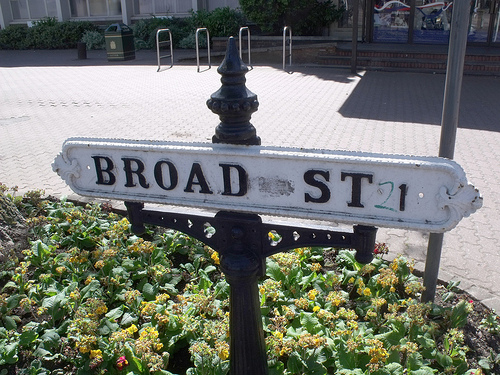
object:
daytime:
[1, 1, 494, 368]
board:
[48, 136, 486, 234]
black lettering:
[90, 154, 247, 197]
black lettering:
[302, 169, 407, 211]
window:
[413, 0, 452, 44]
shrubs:
[135, 35, 151, 48]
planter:
[1, 39, 331, 60]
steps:
[315, 54, 499, 77]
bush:
[27, 16, 99, 50]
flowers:
[101, 315, 178, 369]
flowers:
[288, 260, 473, 374]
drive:
[0, 52, 500, 307]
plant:
[0, 26, 30, 49]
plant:
[238, 0, 351, 36]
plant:
[203, 8, 233, 36]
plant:
[186, 7, 206, 33]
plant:
[78, 32, 107, 49]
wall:
[1, 2, 249, 24]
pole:
[199, 35, 271, 373]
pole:
[418, 0, 482, 305]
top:
[216, 37, 249, 73]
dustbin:
[104, 22, 136, 62]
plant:
[428, 319, 500, 375]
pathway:
[2, 67, 499, 288]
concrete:
[3, 43, 75, 65]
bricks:
[444, 243, 482, 274]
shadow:
[331, 57, 500, 136]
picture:
[0, 4, 500, 375]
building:
[1, 1, 213, 55]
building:
[250, 1, 499, 69]